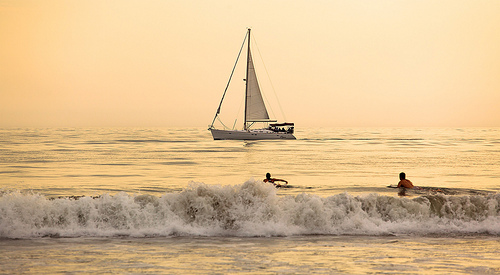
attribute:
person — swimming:
[394, 170, 415, 187]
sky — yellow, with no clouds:
[336, 71, 376, 110]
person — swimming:
[395, 170, 415, 195]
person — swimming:
[257, 167, 291, 184]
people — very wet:
[257, 167, 417, 197]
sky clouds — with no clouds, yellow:
[20, 16, 181, 116]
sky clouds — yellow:
[293, 17, 476, 129]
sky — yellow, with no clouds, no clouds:
[1, 5, 498, 135]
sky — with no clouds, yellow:
[322, 20, 434, 126]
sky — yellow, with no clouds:
[35, 76, 102, 106]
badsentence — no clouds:
[293, 211, 332, 241]